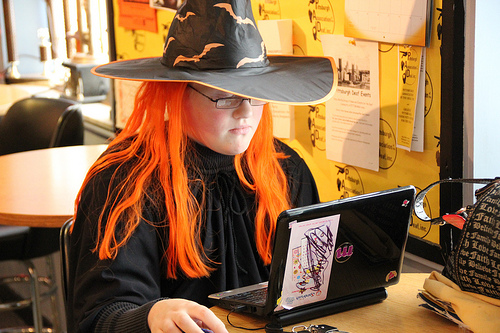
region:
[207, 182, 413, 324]
black laptop computer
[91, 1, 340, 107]
black witch hat with orange bats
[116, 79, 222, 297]
neon orange hair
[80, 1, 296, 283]
young woman in a witch costume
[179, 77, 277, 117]
glasses used for reading or vision correction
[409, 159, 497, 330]
half of a black purse with writing on it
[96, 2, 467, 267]
bulletin board with yellow background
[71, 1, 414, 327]
a young lady using a laptop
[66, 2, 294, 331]
a young dressed up for Halloween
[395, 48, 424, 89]
hands using sign language on a sign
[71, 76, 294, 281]
The woman has orange hair.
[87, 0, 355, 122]
The woman wears a witch's hat.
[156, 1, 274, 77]
The hat has bats on it.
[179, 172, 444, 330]
The woman is working on a laptop.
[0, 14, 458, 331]
The woman is seated in a cafe.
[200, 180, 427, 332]
The laptop is black.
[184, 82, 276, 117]
The woman wears eyeglasses.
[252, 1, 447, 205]
A bulletin board is next to the woman.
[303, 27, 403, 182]
Paper is attached to the bulletin board.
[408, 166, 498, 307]
The woman's bag is on the table.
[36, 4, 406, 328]
witch is doing techno magic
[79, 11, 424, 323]
what happens when you dont get into hogwarts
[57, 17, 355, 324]
american hogwarts clearly underfunded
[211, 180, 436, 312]
laptop is black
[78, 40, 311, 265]
witch hair is blood orange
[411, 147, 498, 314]
purse is black with writing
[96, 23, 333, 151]
hat is orange and black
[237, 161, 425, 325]
laptop is mini and small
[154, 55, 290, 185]
face is white and red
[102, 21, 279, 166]
glasses are slim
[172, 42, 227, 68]
Orange bat on black hat.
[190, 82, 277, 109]
Black glasses on woman's face.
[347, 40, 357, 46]
Yellow pin on a bulletin board.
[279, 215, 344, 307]
White piece of paper on a laptop.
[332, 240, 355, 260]
Pink logo on black laptop.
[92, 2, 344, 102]
Black and orange witches hat.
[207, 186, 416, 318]
Black laptop sitting on a table.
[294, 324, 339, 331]
Pair of car keys on a table.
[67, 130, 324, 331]
Black cape on a woman.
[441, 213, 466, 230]
Red tag on a handbag.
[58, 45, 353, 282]
Orange wig on the kid.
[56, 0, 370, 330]
Kid wearing a witch costume.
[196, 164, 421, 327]
Black laptop on the table.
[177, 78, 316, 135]
Glasses on the kid's face.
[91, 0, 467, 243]
Bulletin board behind the kid.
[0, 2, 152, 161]
Photo taken during the day.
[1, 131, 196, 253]
Round table behind the kid.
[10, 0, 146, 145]
Window behind the black chair.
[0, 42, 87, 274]
Empty black chair by the table.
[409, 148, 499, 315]
Purse on the table.